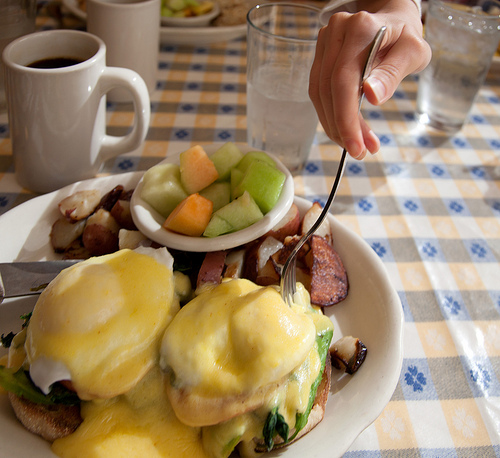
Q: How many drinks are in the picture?
A: Four.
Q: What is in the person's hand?
A: Fork.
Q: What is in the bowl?
A: Fruit.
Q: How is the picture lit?
A: Sun coming from outside.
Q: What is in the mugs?
A: Coffee.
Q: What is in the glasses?
A: Water.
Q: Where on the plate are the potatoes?
A: Under the bowl.